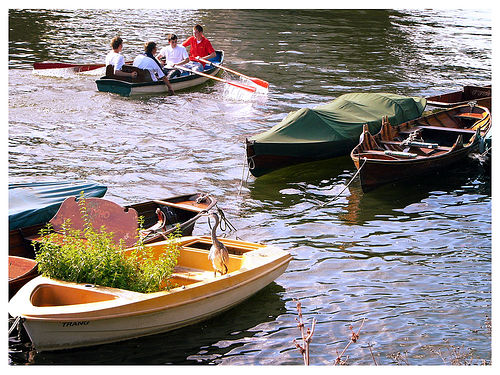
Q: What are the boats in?
A: A body of water.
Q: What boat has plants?
A: The yellow boat.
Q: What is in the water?
A: Boat.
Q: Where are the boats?
A: In the water.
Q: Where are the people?
A: In the boat.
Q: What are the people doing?
A: Rowing a boat.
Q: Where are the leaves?
A: In the boat.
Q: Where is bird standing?
A: In the boat.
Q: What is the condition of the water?
A: Calm.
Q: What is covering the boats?
A: Tarp.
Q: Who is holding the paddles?
A: The people.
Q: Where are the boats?
A: In the water.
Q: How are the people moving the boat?
A: By rowing.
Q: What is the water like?
A: Calm.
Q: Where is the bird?
A: On the boat.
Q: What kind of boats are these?
A: Canoes.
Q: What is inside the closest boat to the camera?
A: Plants.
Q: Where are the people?
A: On the boat.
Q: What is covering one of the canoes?
A: A green tarp.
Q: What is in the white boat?
A: A green plant.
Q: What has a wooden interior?
A: A rowboat.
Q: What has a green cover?
A: A blue boat.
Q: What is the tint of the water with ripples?
A: Blue and green.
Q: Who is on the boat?
A: People.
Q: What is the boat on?
A: Water.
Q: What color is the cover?
A: Green.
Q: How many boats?
A: 6.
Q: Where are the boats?
A: On the water.